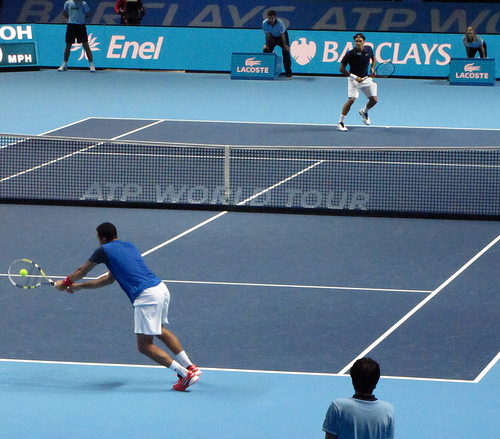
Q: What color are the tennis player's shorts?
A: White.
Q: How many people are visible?
A: Seven.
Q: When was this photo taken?
A: Outside, during the daytime.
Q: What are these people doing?
A: Playing tennis.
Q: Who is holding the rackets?
A: Tennis players.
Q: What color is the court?
A: Blue.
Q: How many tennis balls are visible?
A: One.